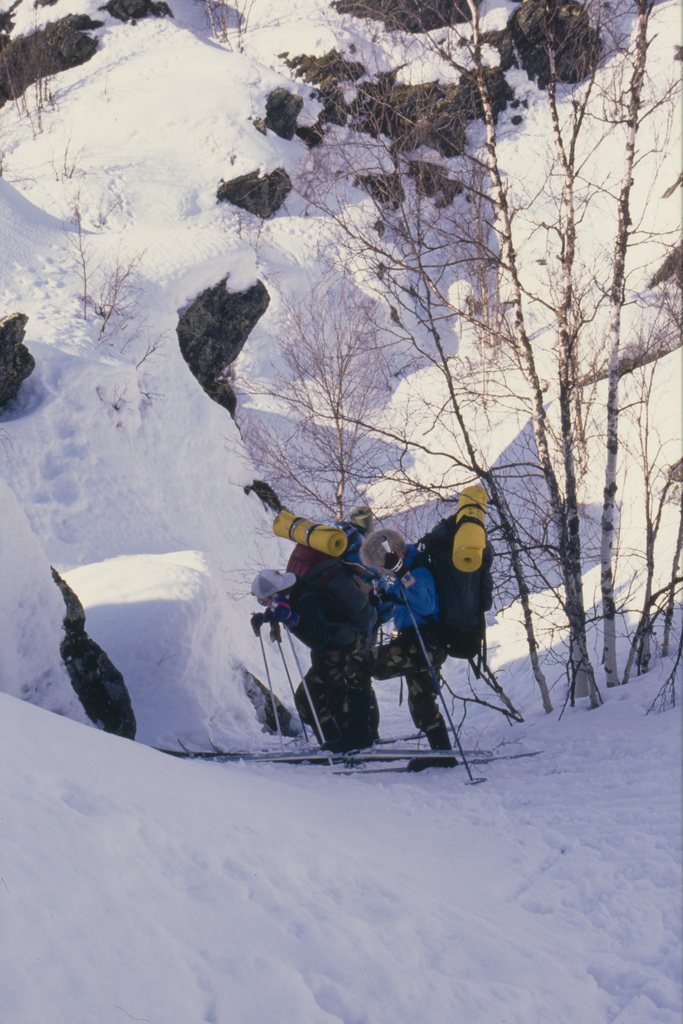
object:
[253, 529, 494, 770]
skiers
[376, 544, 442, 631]
jacket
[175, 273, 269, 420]
rock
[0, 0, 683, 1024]
snow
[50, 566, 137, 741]
rock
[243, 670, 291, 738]
rock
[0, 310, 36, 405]
rock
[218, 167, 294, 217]
rock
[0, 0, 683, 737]
rock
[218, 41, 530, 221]
rock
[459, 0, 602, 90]
rock